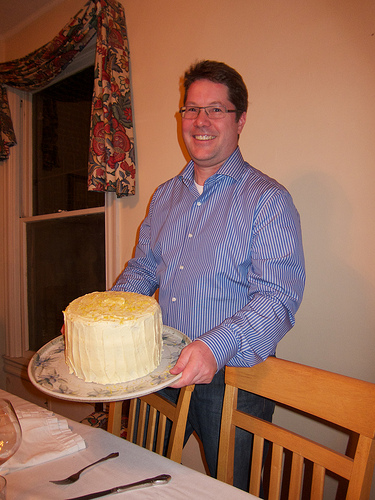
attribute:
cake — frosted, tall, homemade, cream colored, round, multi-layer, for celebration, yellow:
[63, 290, 165, 385]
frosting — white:
[63, 288, 166, 384]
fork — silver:
[51, 450, 121, 488]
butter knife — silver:
[70, 472, 173, 498]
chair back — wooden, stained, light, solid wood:
[218, 355, 373, 499]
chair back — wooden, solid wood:
[109, 382, 194, 466]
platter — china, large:
[29, 324, 197, 403]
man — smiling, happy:
[107, 63, 309, 491]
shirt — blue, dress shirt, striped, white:
[111, 146, 307, 371]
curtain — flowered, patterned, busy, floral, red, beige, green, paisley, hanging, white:
[0, 0, 137, 196]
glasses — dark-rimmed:
[178, 102, 239, 121]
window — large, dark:
[25, 60, 104, 355]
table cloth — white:
[1, 389, 269, 500]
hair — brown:
[182, 60, 248, 121]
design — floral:
[35, 327, 190, 400]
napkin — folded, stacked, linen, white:
[0, 405, 86, 475]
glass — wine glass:
[2, 400, 25, 491]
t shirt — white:
[193, 179, 206, 193]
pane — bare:
[31, 66, 106, 214]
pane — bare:
[24, 213, 107, 350]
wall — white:
[4, 0, 373, 478]